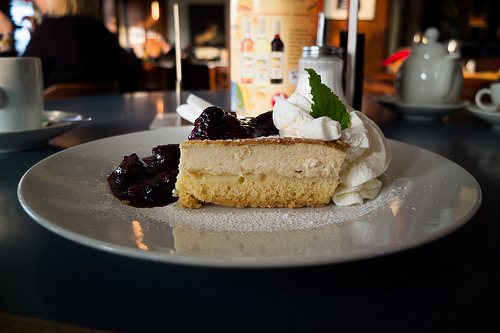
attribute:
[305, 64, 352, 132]
mint leaf — green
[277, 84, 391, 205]
whipped cream — white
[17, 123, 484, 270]
dish — white china, being used, disclike, circular, round, white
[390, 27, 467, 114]
tea kettle — white, on the right, breakable, white porcelain, white china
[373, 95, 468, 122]
dish — white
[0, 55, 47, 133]
coffe mug — on left, white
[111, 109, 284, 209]
fruit topping — dark color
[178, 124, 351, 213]
cake — white, layered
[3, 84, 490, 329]
table — black